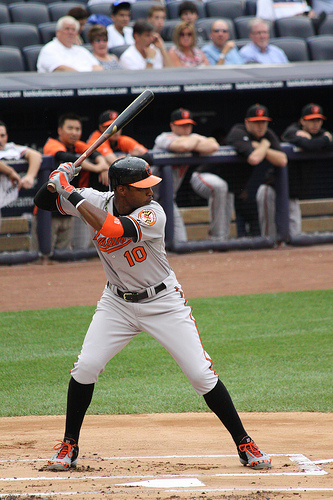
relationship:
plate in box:
[115, 471, 204, 493] [3, 454, 328, 481]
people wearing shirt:
[35, 16, 101, 74] [36, 41, 101, 77]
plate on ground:
[115, 471, 204, 493] [2, 243, 330, 498]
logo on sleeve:
[136, 209, 156, 229] [121, 203, 169, 244]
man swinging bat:
[46, 157, 271, 476] [49, 89, 155, 192]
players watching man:
[191, 101, 289, 248] [46, 157, 271, 476]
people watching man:
[35, 16, 101, 74] [46, 157, 271, 476]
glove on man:
[46, 171, 84, 212] [46, 157, 271, 476]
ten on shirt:
[117, 244, 148, 268] [32, 176, 173, 291]